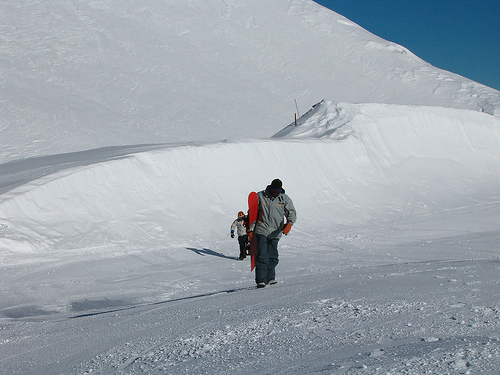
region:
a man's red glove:
[281, 220, 294, 236]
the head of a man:
[269, 177, 284, 192]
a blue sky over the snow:
[310, 0, 496, 90]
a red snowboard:
[240, 184, 265, 279]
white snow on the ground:
[1, 0, 499, 374]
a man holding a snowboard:
[242, 175, 297, 290]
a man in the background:
[228, 207, 253, 260]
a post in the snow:
[289, 109, 299, 126]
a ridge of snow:
[316, 95, 498, 119]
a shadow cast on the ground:
[183, 241, 241, 265]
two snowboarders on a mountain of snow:
[8, 15, 488, 366]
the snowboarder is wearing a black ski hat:
[265, 176, 283, 192]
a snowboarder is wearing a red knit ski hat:
[235, 208, 241, 218]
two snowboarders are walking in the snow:
[230, 177, 301, 287]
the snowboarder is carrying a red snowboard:
[245, 177, 293, 287]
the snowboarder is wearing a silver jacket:
[246, 178, 296, 238]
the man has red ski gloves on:
[245, 221, 290, 239]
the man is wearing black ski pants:
[252, 235, 278, 283]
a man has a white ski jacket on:
[228, 210, 248, 237]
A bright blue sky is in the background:
[8, 0, 498, 368]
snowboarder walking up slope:
[217, 173, 309, 296]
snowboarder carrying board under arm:
[235, 170, 301, 295]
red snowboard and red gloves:
[197, 172, 312, 277]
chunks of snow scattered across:
[120, 290, 472, 365]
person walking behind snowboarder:
[220, 162, 295, 297]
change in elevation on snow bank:
[256, 95, 376, 165]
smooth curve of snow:
[15, 126, 315, 211]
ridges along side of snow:
[346, 105, 481, 175]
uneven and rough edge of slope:
[330, 15, 485, 95]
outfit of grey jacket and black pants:
[245, 172, 300, 292]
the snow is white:
[85, 312, 351, 344]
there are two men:
[228, 168, 313, 318]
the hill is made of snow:
[289, 100, 498, 177]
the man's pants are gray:
[254, 231, 279, 292]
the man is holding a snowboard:
[241, 183, 273, 290]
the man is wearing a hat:
[243, 173, 305, 298]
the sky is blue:
[456, 53, 481, 69]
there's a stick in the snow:
[276, 82, 311, 139]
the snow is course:
[198, 305, 423, 354]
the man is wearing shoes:
[246, 269, 289, 296]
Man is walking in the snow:
[188, 146, 368, 316]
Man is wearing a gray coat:
[251, 177, 310, 257]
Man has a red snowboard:
[237, 180, 267, 281]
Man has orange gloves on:
[272, 213, 312, 241]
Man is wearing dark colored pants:
[239, 230, 290, 294]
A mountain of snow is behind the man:
[81, 0, 495, 232]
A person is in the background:
[221, 204, 258, 266]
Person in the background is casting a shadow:
[181, 218, 241, 268]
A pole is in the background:
[287, 91, 307, 133]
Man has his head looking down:
[255, 176, 300, 203]